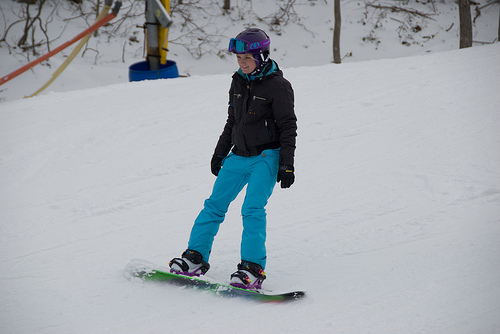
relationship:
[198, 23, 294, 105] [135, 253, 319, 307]
girl on snowboard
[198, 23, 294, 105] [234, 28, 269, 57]
girl wearing helmet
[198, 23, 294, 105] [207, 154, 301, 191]
girl wearing gloves